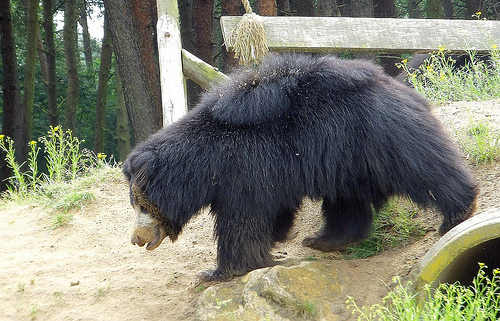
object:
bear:
[123, 53, 480, 280]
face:
[122, 179, 173, 249]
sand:
[0, 196, 499, 320]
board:
[219, 14, 500, 50]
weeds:
[403, 52, 499, 102]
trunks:
[101, 0, 159, 142]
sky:
[55, 1, 116, 45]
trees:
[85, 9, 119, 162]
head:
[122, 133, 214, 250]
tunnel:
[418, 205, 499, 296]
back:
[192, 59, 438, 155]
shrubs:
[460, 121, 499, 163]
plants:
[42, 124, 70, 183]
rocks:
[198, 258, 334, 320]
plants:
[376, 276, 499, 320]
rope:
[227, 4, 272, 67]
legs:
[208, 190, 284, 282]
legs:
[305, 165, 375, 253]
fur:
[205, 54, 382, 126]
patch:
[133, 200, 156, 226]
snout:
[131, 212, 169, 251]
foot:
[429, 184, 484, 238]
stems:
[61, 134, 88, 185]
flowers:
[0, 127, 10, 141]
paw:
[300, 232, 357, 254]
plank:
[183, 50, 224, 98]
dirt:
[146, 208, 170, 225]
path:
[6, 98, 492, 316]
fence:
[155, 1, 498, 124]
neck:
[157, 122, 223, 215]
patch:
[61, 189, 96, 212]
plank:
[153, 0, 189, 124]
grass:
[455, 120, 497, 144]